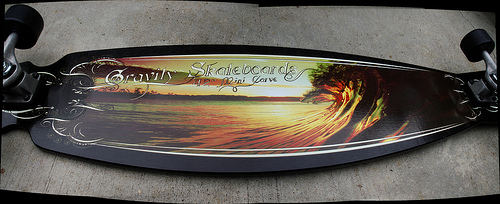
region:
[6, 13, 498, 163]
an artfully designed skateboard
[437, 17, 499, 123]
black skateboard wheel on the right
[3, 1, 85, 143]
black skateboard wheel on the left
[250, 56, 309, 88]
the sun shown in the painting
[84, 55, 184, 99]
the word Gravity on the skateboard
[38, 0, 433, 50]
the grey concrete above the skateboard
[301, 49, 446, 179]
the cresting wave in the painting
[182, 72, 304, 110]
the name of the artist of the painting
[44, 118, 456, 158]
the lower white border of the painting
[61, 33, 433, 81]
the upper white boarder of the painting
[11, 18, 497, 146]
the skateboard is on the floor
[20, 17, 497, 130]
the skateboard has four wheels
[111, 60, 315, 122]
the writing says gravity skateboard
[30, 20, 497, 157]
the board is upside down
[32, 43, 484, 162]
the board is made of wood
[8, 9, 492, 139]
there are two visible wheels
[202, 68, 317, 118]
the sun is setting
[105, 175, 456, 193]
the table is wooden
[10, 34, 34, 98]
the metal is silver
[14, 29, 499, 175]
the photo was taken indoors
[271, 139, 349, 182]
edge of a skateboard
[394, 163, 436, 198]
part of a surface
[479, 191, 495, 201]
edge of a surface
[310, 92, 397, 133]
surface of a skateboard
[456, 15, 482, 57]
wheel of a skateboard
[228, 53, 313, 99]
part of some writing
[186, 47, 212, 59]
part of a line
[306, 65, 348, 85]
part of a tree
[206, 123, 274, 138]
part of a shore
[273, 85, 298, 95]
part of the sky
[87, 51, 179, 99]
the word gravity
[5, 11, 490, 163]
an upside down skateboard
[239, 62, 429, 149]
drawing of a wave at sunset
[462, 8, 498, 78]
one skateboard wheel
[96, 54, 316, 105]
the words gravity skateboards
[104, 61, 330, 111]
white script writing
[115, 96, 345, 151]
drawing of water at sunset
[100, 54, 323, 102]
writing on the bottom of a skateboard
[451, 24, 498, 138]
upside down skateboard wheels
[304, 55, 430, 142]
drawing of a wave on the underside of a skateboard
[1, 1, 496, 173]
Skateboard is upside down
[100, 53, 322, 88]
Skater has letters on top.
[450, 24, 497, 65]
Wheel of skateboard is black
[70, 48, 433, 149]
Skateboard has a design.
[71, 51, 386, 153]
Design color is orange, yellow and green.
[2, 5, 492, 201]
Skateboard is on a wood surface.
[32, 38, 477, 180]
Borders of skateboard is black.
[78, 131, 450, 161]
White lines on skateboard.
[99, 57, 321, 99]
Letters on skateboard are white.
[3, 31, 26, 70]
Holders of wheels are metal.